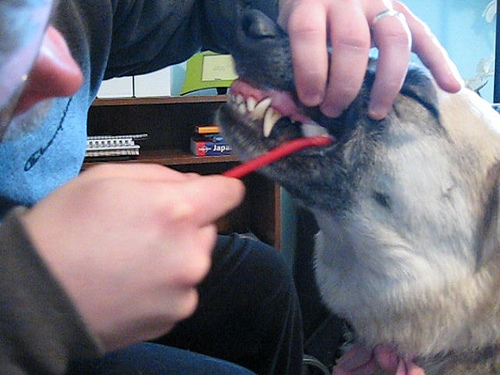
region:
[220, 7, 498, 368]
The person is brushing the dog's teeth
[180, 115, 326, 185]
The toothbrush is red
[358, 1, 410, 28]
The person is wearing a ring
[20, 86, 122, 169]
The brand on the person's sweater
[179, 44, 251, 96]
The green photo frame on the bookshelf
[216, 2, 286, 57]
The nose of the dog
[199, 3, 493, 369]
this is a dog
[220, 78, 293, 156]
teeth of the dog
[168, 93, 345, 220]
this is a toothbrush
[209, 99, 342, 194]
the toothbrush is red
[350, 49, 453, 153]
dogs eye is closed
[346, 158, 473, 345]
the dog is white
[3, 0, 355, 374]
a person bent over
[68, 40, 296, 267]
book case in the background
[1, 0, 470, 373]
person brushing teeth of dog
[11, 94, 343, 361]
hand holding red toothbursh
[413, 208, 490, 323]
tan haired dog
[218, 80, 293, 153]
teeth of dog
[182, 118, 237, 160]
books on book shelf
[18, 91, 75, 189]
sport logo on shirt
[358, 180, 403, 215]
black spot on dog fur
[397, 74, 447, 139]
eye of tan dog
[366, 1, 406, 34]
ring on finger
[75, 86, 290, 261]
wooden shelf with books on it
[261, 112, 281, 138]
this is a tooth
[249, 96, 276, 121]
this is a tooth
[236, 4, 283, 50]
this is a dog`s nose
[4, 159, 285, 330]
this is a hand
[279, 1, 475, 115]
this is a hand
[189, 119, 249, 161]
these are books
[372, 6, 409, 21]
this is a ring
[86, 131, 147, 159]
these are books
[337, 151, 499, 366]
this is dog`s fur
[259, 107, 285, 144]
Tooth of a dog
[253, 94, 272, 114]
Tooth of a dog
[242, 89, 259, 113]
Tooth of a dog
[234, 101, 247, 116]
Tooth of a dog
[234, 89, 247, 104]
Tooth of a dog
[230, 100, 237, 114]
Tooth of a dog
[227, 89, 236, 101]
Tooth of a dog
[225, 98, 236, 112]
Tooth of a dog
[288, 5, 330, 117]
Finger of a person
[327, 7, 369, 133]
Finger of a person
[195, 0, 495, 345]
dog with teeth showing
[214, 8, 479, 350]
dog getting his teeth brushed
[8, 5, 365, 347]
man holding red toothvrush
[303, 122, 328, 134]
white bristles on the toothbrush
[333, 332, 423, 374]
pink bow the dog is wearing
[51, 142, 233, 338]
hand holding the toothbrush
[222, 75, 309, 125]
pink gums of the dog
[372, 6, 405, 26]
ring on the person's finger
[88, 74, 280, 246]
desk behind the person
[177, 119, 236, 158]
books stacked on the desk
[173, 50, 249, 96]
green frame on the desk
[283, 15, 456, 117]
fingers holding the dog's mouth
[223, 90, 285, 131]
teeth in the dog's mouth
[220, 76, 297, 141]
teeth on the dog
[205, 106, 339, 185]
red toothbrush in the dog's mouth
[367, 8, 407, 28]
silver ring on the finger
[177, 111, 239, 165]
books on the shelf